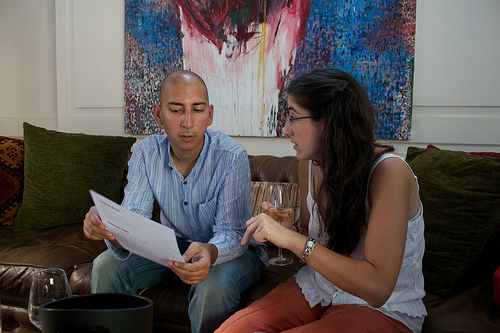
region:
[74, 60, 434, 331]
a man and a woman sitting on couch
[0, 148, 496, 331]
a brown couch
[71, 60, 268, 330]
a man is holding white piece of paper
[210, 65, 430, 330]
a woman holding a wine glass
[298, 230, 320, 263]
a silver watch with white face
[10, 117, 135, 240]
a green throw pillow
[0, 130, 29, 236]
a brown, red and black pillow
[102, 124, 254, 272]
a blue striped shirt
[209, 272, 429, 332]
a woman wearing orange pants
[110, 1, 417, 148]
a multi colored piece of art on wall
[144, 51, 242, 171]
a man with a bald head.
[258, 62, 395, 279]
a woman with long dark hair.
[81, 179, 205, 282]
a white piece of paper.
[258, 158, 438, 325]
a white tank top.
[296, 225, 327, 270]
A metal wrist watch.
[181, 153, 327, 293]
a pillow on a couch.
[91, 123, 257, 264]
a man wearing a blue stripe shirt.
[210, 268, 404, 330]
a pair of pants.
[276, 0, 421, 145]
a section of blue painting.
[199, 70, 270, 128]
the middle of a painting.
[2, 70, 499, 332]
two people sitting on a couch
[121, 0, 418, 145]
a colorful painting on the wall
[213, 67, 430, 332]
the woman is holding a wine glass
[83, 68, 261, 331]
the man is holding a piece of paper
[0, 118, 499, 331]
the couch is brown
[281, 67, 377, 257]
the woman has long brown hair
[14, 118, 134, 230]
the pillow is green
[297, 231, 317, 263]
the wrist watch is silver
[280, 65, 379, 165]
the woman is wearing glasses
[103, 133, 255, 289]
the man's shirt is blue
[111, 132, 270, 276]
Man's blue and white striped shirt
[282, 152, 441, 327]
White shirt on woman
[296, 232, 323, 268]
Bracelet on woman's arm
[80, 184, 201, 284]
Paper in man's hands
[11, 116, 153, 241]
Green pillow on couch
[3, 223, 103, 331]
Brown couch people are sitting on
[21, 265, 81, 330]
Clear top of wine glass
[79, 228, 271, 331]
Blue jeans man is wearing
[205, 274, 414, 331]
Salmon pants woman is wearing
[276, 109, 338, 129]
Eye glasses on woman's face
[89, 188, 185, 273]
a white document in the mans hands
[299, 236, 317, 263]
the girl is wearing a wrist watch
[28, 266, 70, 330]
a clear wine goblet on the table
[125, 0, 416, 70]
an abstract art hanging on the wall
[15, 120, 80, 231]
a green sofa pillow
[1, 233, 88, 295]
a brown leather sofa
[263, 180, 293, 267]
the girl is holding a wine goblet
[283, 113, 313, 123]
the girl is wearing black framed glasses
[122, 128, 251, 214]
the man is wearing a blue button down shirt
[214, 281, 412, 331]
the girl is wearing brown pants